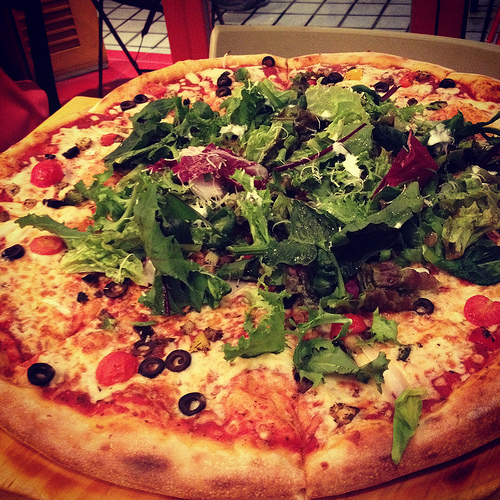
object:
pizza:
[0, 50, 499, 499]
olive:
[261, 56, 275, 68]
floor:
[97, 2, 500, 53]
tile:
[283, 2, 320, 15]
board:
[1, 20, 498, 497]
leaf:
[304, 85, 363, 119]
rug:
[0, 45, 174, 153]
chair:
[205, 14, 500, 83]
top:
[210, 24, 499, 82]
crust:
[1, 50, 498, 499]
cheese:
[2, 49, 499, 498]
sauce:
[0, 63, 497, 457]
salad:
[77, 70, 500, 346]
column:
[158, 2, 215, 62]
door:
[6, 2, 110, 84]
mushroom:
[330, 401, 360, 430]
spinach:
[421, 235, 499, 297]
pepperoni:
[30, 235, 63, 256]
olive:
[374, 81, 389, 93]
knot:
[441, 461, 472, 490]